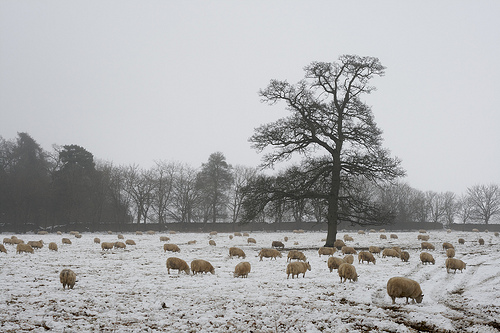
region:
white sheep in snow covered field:
[62, 270, 76, 285]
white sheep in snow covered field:
[166, 260, 189, 273]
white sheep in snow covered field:
[190, 260, 212, 274]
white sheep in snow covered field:
[235, 265, 252, 277]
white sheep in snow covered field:
[282, 259, 313, 277]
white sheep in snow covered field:
[337, 265, 357, 283]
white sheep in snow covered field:
[386, 276, 423, 303]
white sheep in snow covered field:
[446, 259, 466, 271]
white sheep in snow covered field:
[422, 251, 431, 266]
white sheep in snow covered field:
[358, 253, 375, 262]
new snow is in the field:
[1, 223, 498, 332]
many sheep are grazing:
[0, 220, 490, 310]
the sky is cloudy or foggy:
[1, 2, 498, 218]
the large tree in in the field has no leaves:
[232, 50, 410, 256]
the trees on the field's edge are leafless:
[2, 135, 495, 231]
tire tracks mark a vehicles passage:
[371, 233, 496, 329]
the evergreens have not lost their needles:
[5, 128, 110, 233]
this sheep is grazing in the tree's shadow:
[266, 236, 283, 251]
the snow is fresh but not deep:
[0, 220, 496, 325]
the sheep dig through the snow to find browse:
[1, 220, 491, 320]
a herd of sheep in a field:
[12, 226, 479, 296]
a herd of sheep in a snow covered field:
[19, 225, 483, 301]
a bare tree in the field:
[254, 48, 417, 269]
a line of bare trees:
[15, 160, 270, 222]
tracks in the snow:
[372, 239, 489, 311]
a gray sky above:
[10, 3, 314, 135]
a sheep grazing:
[387, 276, 425, 312]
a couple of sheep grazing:
[156, 253, 213, 282]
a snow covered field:
[143, 281, 255, 323]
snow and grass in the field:
[123, 286, 226, 324]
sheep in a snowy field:
[2, 214, 498, 307]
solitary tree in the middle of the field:
[250, 46, 399, 253]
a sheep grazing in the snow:
[384, 275, 424, 306]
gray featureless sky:
[7, 4, 498, 196]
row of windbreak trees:
[131, 155, 497, 225]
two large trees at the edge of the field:
[6, 131, 138, 235]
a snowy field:
[2, 230, 498, 329]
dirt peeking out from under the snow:
[294, 290, 498, 330]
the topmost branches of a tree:
[308, 51, 383, 97]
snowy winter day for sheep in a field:
[2, 131, 492, 329]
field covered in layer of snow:
[7, 216, 487, 331]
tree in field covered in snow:
[243, 59, 390, 254]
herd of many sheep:
[3, 217, 483, 312]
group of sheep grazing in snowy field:
[2, 222, 480, 319]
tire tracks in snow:
[365, 236, 495, 324]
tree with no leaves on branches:
[253, 57, 402, 254]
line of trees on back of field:
[7, 140, 491, 226]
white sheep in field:
[8, 219, 491, 306]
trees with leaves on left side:
[7, 132, 127, 228]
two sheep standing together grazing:
[164, 252, 214, 281]